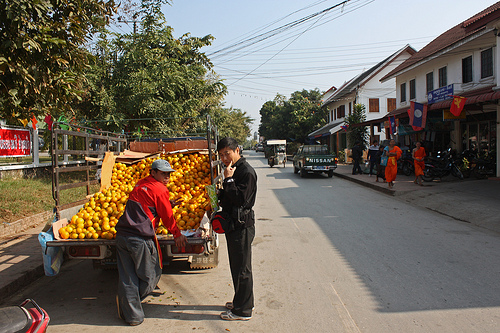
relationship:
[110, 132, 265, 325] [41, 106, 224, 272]
men next to truck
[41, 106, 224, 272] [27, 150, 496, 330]
truck on street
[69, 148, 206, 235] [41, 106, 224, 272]
oranges in truck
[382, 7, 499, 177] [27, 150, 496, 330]
building next to street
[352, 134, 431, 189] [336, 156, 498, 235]
people on sidewalk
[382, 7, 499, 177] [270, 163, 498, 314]
building casting shadow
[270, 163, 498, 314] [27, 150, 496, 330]
shadow on street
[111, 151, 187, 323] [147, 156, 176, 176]
man wearing hat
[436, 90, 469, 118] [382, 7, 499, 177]
flag from building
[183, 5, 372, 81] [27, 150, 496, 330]
power lines above street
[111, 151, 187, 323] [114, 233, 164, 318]
man with pants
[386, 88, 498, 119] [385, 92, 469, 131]
awning has flags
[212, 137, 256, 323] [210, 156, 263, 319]
men with outfit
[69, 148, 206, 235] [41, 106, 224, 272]
oranges on truck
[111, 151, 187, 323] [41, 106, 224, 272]
man on back of truck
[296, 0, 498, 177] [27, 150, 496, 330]
buildings beside street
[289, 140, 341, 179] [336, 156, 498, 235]
truck beside sidewalk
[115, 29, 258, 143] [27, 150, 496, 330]
trees beside street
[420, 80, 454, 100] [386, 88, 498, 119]
poster on awning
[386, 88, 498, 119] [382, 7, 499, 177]
awning of building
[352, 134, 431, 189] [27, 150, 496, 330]
people on side of street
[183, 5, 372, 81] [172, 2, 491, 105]
power lines in sky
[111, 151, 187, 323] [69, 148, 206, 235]
man in front of oranges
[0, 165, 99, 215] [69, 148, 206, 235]
grass left of oranges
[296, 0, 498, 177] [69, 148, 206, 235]
buildings right of oranges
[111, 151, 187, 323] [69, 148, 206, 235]
man selling oranges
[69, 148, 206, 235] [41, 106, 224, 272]
oranges out of truck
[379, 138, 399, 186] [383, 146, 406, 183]
lady in dress